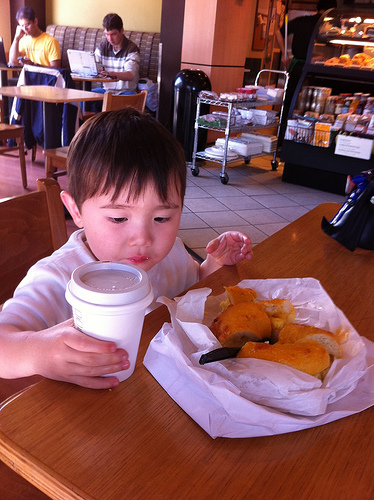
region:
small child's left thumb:
[206, 236, 219, 251]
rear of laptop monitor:
[65, 47, 98, 77]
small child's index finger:
[61, 325, 116, 354]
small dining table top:
[2, 82, 104, 103]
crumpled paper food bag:
[152, 274, 369, 439]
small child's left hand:
[203, 228, 252, 263]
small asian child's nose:
[127, 225, 148, 244]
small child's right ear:
[57, 187, 80, 228]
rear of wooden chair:
[99, 89, 146, 108]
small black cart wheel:
[219, 170, 229, 184]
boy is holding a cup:
[51, 114, 221, 367]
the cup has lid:
[54, 249, 137, 398]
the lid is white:
[64, 256, 166, 319]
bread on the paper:
[208, 274, 334, 420]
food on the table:
[167, 266, 346, 439]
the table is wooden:
[21, 383, 230, 478]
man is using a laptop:
[71, 0, 159, 114]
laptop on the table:
[62, 27, 137, 113]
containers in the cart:
[199, 71, 304, 194]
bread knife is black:
[204, 321, 277, 384]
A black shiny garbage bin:
[174, 65, 214, 172]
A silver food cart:
[202, 65, 288, 184]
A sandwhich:
[214, 289, 342, 387]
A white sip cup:
[64, 261, 153, 382]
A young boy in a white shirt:
[0, 115, 261, 390]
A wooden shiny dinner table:
[0, 196, 372, 489]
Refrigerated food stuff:
[296, 8, 372, 170]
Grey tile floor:
[214, 198, 271, 225]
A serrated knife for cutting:
[195, 332, 314, 366]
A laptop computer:
[64, 44, 114, 79]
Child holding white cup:
[0, 105, 252, 390]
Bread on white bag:
[210, 298, 273, 348]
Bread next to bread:
[211, 300, 274, 342]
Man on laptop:
[79, 12, 143, 102]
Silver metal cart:
[185, 65, 288, 184]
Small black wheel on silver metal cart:
[218, 172, 230, 183]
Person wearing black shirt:
[267, 0, 329, 149]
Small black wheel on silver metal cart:
[189, 164, 201, 175]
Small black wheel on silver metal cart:
[269, 158, 279, 170]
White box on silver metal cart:
[217, 133, 262, 154]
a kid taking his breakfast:
[32, 117, 342, 467]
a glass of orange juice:
[62, 264, 146, 397]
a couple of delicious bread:
[226, 286, 346, 382]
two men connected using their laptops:
[9, 9, 136, 91]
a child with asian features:
[61, 110, 208, 266]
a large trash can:
[176, 63, 205, 158]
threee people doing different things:
[7, 6, 189, 378]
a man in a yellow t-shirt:
[9, 8, 65, 63]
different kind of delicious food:
[296, 5, 371, 162]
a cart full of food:
[192, 79, 290, 197]